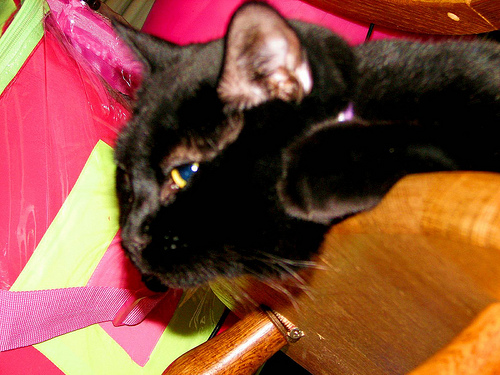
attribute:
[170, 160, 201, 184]
eye — yellow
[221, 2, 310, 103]
ear — pink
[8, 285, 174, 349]
strap — pink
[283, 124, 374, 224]
paw — dark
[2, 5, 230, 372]
pattern — colorful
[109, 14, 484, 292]
cat — black, dark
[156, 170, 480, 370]
chair — brown, wooden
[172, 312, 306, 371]
leg — brown, wooden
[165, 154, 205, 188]
reflection — light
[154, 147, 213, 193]
eye — cat's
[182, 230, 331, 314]
whiskers — white, cat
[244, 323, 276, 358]
reflection — light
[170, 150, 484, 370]
stool leg — stool's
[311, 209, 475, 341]
chair — bottom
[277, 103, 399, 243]
paw — front paw, cat's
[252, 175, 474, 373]
table — wooden, bottom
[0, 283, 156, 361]
strap — pink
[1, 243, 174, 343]
leash — cat's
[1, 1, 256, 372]
package — pink, green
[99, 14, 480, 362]
cat — black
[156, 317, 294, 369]
leg — table leg, wooden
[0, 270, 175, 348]
strap — pink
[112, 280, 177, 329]
buckle — pink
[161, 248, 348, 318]
whiskers — white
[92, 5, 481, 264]
cat — black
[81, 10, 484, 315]
kitten — black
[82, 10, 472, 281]
kitten — sleepy